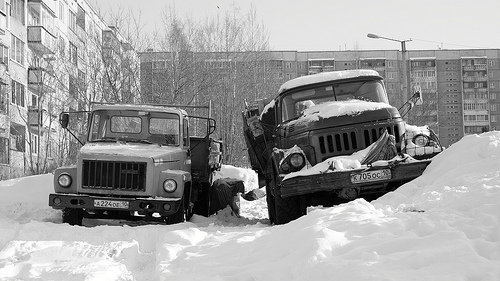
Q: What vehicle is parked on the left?
A: A small truck.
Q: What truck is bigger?
A: The truck on the right.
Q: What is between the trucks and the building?
A: A tree with no leaves.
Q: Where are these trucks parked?
A: On the snow.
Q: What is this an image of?
A: Trucks with snow on them.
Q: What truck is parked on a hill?
A: The one on the right.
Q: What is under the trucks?
A: Snow.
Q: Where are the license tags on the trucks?
A: On the front bumpers.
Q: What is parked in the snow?
A: Trucks.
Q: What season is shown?
A: Winter.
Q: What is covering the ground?
A: Snow.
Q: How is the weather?
A: Sunny.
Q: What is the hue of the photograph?
A: Black and white.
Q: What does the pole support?
A: Street light.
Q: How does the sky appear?
A: White.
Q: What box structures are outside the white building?
A: Balconies.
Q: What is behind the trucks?
A: Building.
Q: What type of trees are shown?
A: Leafless.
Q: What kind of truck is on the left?
A: A grey truck with old flat bed.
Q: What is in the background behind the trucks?
A: A building with balconies.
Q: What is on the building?
A: Balconies.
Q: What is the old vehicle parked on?
A: Snow.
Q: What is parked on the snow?
A: Two old vehicles.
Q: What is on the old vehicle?
A: Snow.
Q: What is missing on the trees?
A: Leaves.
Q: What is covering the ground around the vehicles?
A: Snow.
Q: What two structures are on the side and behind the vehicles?
A: Buildings with balconies.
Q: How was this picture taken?
A: In black and white.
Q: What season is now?
A: Winter.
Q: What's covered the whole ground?
A: Snow.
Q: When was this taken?
A: Winter.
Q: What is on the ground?
A: Snow.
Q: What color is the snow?
A: White.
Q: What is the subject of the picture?
A: Two old trucks.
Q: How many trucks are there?
A: 2.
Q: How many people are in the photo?
A: Zero.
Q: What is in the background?
A: Buildings.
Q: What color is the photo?
A: Black and white.